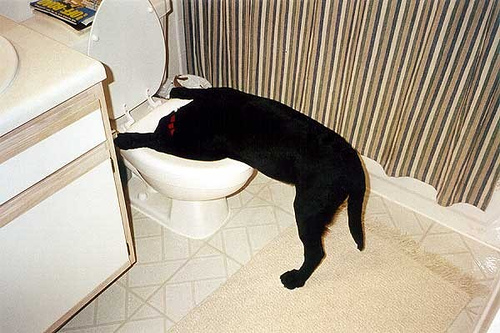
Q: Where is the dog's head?
A: In the toilet.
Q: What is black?
A: Dog.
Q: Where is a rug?
A: On the floor.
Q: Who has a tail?
A: A dog.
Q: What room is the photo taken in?
A: Bathroom.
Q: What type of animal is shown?
A: Dog.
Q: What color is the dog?
A: Black.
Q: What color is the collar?
A: Red.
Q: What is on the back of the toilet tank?
A: Magazines.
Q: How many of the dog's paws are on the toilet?
A: 2.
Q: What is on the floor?
A: Rug.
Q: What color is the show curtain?
A: Tan, brown and black.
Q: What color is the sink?
A: White.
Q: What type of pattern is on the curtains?
A: Stripes.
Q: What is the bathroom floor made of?
A: Tiles.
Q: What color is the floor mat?
A: Light brown.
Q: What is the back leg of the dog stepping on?
A: The floor mat.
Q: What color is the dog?
A: Black.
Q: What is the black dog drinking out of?
A: The toilet.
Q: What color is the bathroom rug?
A: Beige.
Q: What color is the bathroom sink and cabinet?
A: Beige and white.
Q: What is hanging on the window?
A: Striped bathroom curtains.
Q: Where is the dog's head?
A: In a toilet bowl.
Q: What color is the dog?
A: Black.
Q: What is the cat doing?
A: Putting his head in the toilet bowl.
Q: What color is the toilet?
A: White.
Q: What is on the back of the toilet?
A: Magazines.